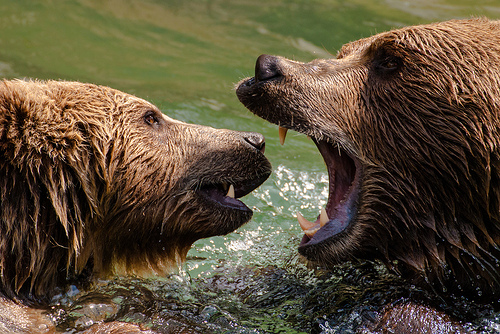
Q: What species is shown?
A: Grizzly bear.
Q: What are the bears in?
A: Water.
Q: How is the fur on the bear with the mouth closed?
A: Wet.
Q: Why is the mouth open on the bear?
A: To bite another bear.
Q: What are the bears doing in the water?
A: Playing.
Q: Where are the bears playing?
A: River.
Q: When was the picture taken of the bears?
A: Vacationing at a wildlife park.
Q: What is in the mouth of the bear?
A: Sharp teeth.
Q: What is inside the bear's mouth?
A: Teeth.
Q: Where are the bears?
A: In water.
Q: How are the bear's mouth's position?
A: Open.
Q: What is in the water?
A: Bears.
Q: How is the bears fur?
A: Wet.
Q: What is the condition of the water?
A: Calm.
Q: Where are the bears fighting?
A: Water.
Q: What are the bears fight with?
A: Their mouths.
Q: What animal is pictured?
A: Bears.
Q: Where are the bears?
A: In the water.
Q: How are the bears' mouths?
A: Open and agape.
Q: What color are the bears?
A: Brown.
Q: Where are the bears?
A: Water.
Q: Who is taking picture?
A: Photographer.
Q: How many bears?
A: Two.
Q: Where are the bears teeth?
A: Mouth.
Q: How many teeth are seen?
A: Four.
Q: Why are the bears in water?
A: Swimming.